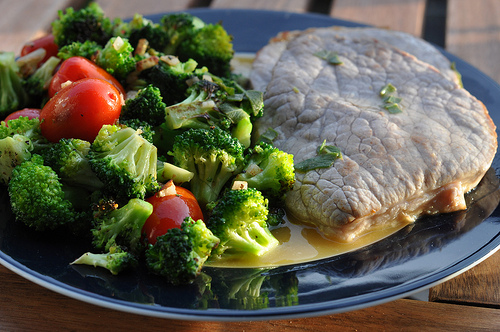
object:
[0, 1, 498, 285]
meal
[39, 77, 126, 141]
tomato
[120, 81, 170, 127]
broccoli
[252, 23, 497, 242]
meat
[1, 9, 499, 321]
plate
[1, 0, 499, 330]
table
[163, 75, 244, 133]
vegetables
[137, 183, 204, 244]
tomato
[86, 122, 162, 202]
broccoli